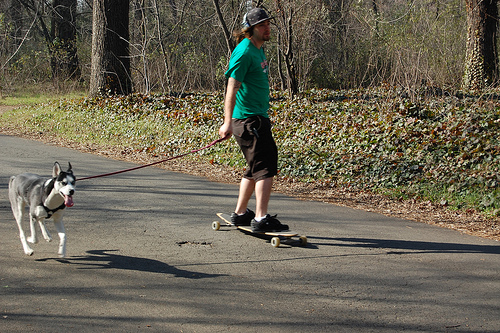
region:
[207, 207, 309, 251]
Long board skateboard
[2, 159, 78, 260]
Black and white dog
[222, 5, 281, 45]
Man with long hair wearing hat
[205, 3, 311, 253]
Man riding a skateboard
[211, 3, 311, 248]
Man wearing green shirt and shorts riding skateboard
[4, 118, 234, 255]
Dog on a leash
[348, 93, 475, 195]
Leaves and grass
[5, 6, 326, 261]
Dog running along skateboarder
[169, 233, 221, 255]
Pothole in ashphalt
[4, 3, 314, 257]
Man on a skateboard holding leash for a dog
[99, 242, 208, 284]
a shadow on the ground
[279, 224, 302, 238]
a skateboard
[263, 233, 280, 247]
a wheel on the skateboard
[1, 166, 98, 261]
a dog running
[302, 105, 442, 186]
the leaves are green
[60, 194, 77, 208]
the dogs tongue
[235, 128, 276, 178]
man is wearing shorts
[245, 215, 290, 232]
black shoe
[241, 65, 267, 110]
man is wearing a green shirt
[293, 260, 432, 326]
the street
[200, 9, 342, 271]
the man is skateboarding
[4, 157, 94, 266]
the dog is walking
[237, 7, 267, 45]
man has black cap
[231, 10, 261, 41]
man is wearing headphones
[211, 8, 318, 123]
man has green shirt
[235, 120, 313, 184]
man has brown shorts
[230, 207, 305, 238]
man has white socks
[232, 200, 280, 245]
man has black shoes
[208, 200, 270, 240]
man on black skateboard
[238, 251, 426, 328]
road is light grey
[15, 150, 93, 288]
white and grey dog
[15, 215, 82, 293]
dog has white paws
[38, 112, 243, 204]
this is a leash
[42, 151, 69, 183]
this is an ear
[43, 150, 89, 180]
these are the ears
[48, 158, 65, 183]
this is a dog ear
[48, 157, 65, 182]
this is the right ear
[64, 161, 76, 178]
this is the left ear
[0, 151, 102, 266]
this is a dog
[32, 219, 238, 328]
this is a shadow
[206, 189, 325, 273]
this is a skateboard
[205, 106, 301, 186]
these are the shorts